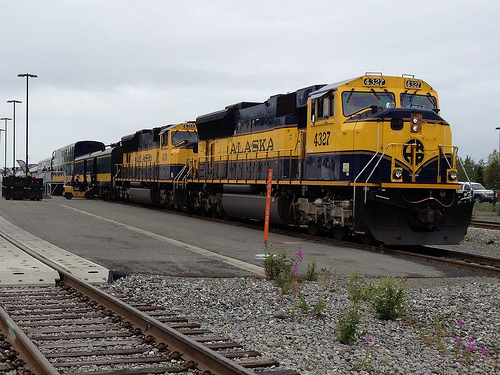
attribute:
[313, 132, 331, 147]
4327 — black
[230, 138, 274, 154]
alaska — black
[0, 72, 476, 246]
train — yellow, black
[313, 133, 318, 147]
4 — black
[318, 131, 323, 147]
3 — black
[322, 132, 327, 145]
2 — black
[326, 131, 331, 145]
7 — black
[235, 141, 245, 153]
l — black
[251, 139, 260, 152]
s — black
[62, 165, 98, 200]
forklift — yellow, small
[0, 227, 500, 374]
gravel — grey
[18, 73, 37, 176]
light pole — tall, off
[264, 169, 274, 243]
warning sign — plastic, flourescent orange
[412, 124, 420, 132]
center headlight — off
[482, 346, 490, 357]
flower — purple, small, growing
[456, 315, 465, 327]
flower — purple, small, growing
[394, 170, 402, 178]
headlight — off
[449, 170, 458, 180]
headlight — off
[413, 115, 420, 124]
center headlight — off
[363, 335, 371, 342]
flower — growing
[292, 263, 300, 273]
flower — growing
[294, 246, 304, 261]
flower — growing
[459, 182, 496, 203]
car — parked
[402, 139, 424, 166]
symbol — round, black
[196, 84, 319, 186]
train car — yellow, black